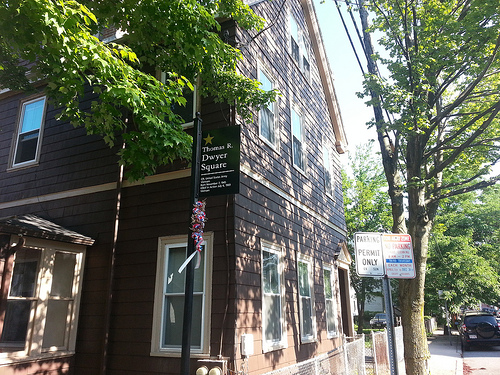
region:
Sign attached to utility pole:
[196, 121, 240, 194]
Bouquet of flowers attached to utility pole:
[192, 192, 202, 262]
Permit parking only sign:
[348, 231, 388, 284]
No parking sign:
[383, 227, 418, 280]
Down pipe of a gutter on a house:
[95, 191, 121, 363]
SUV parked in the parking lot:
[454, 307, 499, 349]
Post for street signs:
[376, 278, 398, 373]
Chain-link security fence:
[255, 332, 370, 374]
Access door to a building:
[332, 248, 360, 353]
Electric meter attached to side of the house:
[190, 354, 228, 374]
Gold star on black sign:
[186, 126, 240, 197]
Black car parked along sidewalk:
[442, 306, 499, 355]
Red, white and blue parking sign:
[381, 229, 416, 286]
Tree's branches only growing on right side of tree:
[366, 24, 499, 356]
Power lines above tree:
[318, 0, 400, 120]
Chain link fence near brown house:
[315, 315, 411, 374]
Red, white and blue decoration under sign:
[181, 196, 219, 272]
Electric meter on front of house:
[195, 353, 229, 373]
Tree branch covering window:
[87, 5, 229, 149]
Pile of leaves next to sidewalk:
[451, 353, 488, 372]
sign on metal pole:
[196, 125, 241, 202]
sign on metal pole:
[347, 237, 381, 279]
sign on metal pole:
[386, 235, 411, 284]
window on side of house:
[157, 252, 212, 357]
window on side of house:
[253, 249, 282, 346]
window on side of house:
[286, 257, 316, 344]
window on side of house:
[316, 265, 336, 335]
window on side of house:
[287, 102, 309, 172]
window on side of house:
[258, 75, 272, 146]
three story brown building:
[10, 26, 409, 372]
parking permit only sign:
[338, 211, 387, 296]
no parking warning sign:
[373, 227, 424, 288]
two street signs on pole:
[346, 218, 423, 368]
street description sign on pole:
[181, 104, 240, 366]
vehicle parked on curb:
[453, 295, 493, 360]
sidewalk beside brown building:
[409, 320, 461, 373]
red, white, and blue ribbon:
[178, 197, 213, 284]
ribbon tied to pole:
[175, 191, 215, 267]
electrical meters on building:
[184, 353, 236, 373]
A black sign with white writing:
[187, 121, 247, 193]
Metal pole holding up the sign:
[181, 192, 218, 372]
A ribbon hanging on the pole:
[184, 192, 216, 278]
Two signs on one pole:
[337, 219, 460, 339]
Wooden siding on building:
[241, 130, 369, 236]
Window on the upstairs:
[13, 99, 53, 179]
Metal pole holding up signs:
[383, 276, 406, 373]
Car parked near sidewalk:
[458, 304, 496, 350]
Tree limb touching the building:
[36, 57, 243, 162]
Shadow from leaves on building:
[247, 187, 419, 305]